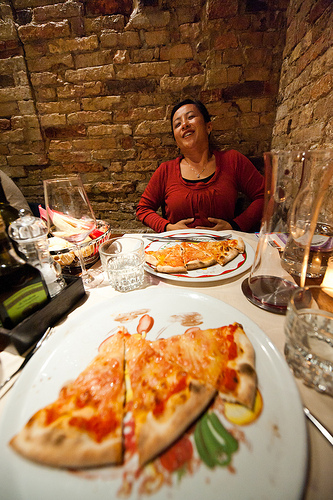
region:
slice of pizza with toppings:
[67, 329, 116, 477]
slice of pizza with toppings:
[125, 340, 194, 423]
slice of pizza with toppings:
[140, 248, 167, 273]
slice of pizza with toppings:
[166, 238, 197, 262]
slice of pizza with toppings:
[194, 239, 226, 269]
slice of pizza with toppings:
[70, 379, 124, 425]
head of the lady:
[158, 91, 223, 160]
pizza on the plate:
[39, 327, 246, 457]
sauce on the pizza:
[49, 382, 122, 426]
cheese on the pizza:
[120, 346, 174, 395]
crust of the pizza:
[135, 384, 212, 461]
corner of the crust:
[230, 383, 269, 421]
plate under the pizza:
[236, 392, 319, 475]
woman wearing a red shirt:
[128, 81, 276, 237]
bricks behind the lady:
[71, 71, 157, 146]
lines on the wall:
[77, 14, 183, 105]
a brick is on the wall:
[95, 180, 134, 195]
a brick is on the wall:
[47, 137, 68, 149]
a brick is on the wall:
[91, 203, 113, 209]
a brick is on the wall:
[124, 189, 145, 202]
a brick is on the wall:
[109, 78, 156, 93]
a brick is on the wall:
[110, 112, 126, 137]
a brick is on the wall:
[137, 135, 155, 145]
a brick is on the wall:
[292, 124, 327, 141]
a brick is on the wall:
[9, 154, 55, 165]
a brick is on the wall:
[47, 145, 72, 150]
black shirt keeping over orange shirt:
[175, 169, 224, 188]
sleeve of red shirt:
[145, 209, 183, 233]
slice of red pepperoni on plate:
[161, 439, 196, 471]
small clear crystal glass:
[93, 238, 156, 287]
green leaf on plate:
[190, 410, 243, 472]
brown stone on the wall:
[69, 43, 155, 114]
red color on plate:
[188, 267, 224, 280]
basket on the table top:
[42, 212, 111, 274]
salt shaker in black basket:
[6, 199, 89, 304]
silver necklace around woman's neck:
[179, 153, 227, 184]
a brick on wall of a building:
[72, 111, 111, 119]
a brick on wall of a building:
[110, 162, 120, 167]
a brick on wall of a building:
[117, 128, 133, 135]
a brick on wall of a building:
[143, 120, 178, 135]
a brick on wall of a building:
[119, 150, 141, 158]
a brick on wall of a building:
[17, 99, 36, 118]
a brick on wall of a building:
[38, 103, 61, 114]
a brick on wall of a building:
[222, 75, 271, 103]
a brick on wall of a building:
[172, 59, 210, 80]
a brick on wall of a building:
[135, 48, 156, 60]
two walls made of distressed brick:
[1, 1, 330, 227]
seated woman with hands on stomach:
[135, 98, 270, 231]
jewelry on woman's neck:
[184, 154, 212, 177]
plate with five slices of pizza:
[143, 229, 252, 281]